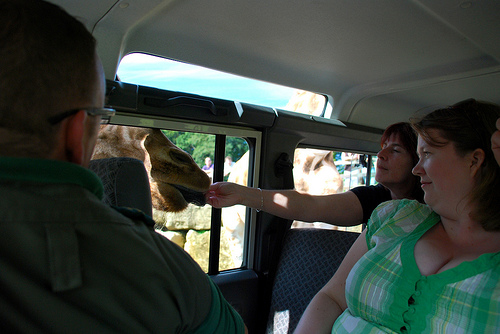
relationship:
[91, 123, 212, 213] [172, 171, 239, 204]
animal with nose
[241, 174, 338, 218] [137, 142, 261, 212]
hand touching giraffe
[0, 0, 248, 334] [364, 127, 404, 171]
man wearing glasses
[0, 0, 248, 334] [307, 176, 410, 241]
man wearing coat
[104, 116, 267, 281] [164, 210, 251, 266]
window of car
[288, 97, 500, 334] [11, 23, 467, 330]
woman sitting car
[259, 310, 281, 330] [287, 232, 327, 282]
sun on seat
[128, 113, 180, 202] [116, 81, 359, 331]
head in window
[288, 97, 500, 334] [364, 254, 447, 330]
woman in shirt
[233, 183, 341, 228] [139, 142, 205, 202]
arm feeding giraffe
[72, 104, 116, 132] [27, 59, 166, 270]
eyeglasses on man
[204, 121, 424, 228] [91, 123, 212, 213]
woman feeding animal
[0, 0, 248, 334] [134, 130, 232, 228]
man looking at giraffe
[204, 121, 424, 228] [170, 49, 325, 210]
woman in car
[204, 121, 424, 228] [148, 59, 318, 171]
woman in car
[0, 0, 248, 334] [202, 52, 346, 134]
man in car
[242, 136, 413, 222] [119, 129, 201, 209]
woman feeding giraffe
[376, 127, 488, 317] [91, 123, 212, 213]
woman watching animal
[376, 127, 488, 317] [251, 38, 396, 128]
woman in car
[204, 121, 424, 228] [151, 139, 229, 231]
woman feeding animal